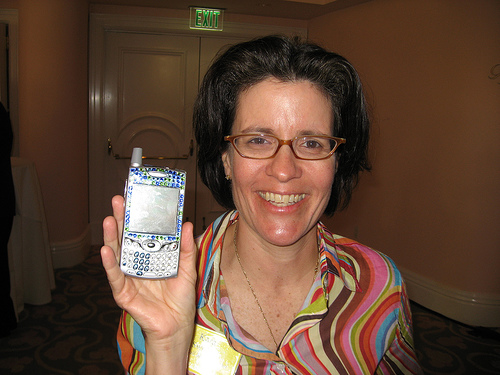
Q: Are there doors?
A: Yes, there are doors.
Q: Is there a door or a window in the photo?
A: Yes, there are doors.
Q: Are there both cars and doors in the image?
A: No, there are doors but no cars.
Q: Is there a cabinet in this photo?
A: No, there are no cabinets.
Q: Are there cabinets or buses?
A: No, there are no cabinets or buses.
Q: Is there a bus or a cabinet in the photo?
A: No, there are no cabinets or buses.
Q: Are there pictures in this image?
A: No, there are no pictures.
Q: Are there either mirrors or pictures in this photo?
A: No, there are no pictures or mirrors.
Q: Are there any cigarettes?
A: No, there are no cigarettes.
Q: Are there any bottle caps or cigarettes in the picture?
A: No, there are no cigarettes or bottle caps.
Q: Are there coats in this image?
A: Yes, there is a coat.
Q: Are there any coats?
A: Yes, there is a coat.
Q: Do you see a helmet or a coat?
A: Yes, there is a coat.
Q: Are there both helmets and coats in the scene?
A: No, there is a coat but no helmets.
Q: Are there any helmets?
A: No, there are no helmets.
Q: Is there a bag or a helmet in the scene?
A: No, there are no helmets or bags.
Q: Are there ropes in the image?
A: No, there are no ropes.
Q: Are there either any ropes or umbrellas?
A: No, there are no ropes or umbrellas.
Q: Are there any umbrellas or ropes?
A: No, there are no ropes or umbrellas.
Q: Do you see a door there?
A: Yes, there is a door.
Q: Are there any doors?
A: Yes, there is a door.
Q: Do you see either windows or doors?
A: Yes, there is a door.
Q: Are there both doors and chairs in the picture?
A: No, there is a door but no chairs.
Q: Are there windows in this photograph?
A: No, there are no windows.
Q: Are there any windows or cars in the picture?
A: No, there are no windows or cars.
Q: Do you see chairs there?
A: No, there are no chairs.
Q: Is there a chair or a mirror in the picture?
A: No, there are no chairs or mirrors.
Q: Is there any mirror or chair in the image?
A: No, there are no chairs or mirrors.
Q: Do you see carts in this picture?
A: No, there are no carts.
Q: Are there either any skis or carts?
A: No, there are no carts or skis.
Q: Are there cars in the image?
A: No, there are no cars.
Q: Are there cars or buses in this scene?
A: No, there are no cars or buses.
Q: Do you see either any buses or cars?
A: No, there are no cars or buses.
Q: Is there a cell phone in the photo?
A: Yes, there is a cell phone.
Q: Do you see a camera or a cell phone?
A: Yes, there is a cell phone.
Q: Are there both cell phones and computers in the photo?
A: No, there is a cell phone but no computers.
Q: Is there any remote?
A: No, there are no remote controls.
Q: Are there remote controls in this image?
A: No, there are no remote controls.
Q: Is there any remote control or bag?
A: No, there are no remote controls or bags.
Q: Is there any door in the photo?
A: Yes, there is a door.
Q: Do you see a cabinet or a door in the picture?
A: Yes, there is a door.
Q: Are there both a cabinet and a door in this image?
A: No, there is a door but no cabinets.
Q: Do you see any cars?
A: No, there are no cars.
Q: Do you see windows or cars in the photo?
A: No, there are no cars or windows.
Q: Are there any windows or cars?
A: No, there are no cars or windows.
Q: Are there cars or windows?
A: No, there are no cars or windows.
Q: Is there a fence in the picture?
A: No, there are no fences.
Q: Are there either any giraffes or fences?
A: No, there are no fences or giraffes.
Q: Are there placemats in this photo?
A: No, there are no placemats.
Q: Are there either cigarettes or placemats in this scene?
A: No, there are no placemats or cigarettes.